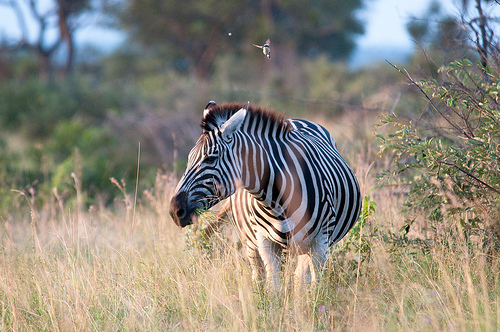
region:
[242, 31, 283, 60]
A small bird in flight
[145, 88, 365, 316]
A zebra standing in tall grass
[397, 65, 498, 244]
Green leafy small bush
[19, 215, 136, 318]
Grass drying in the sun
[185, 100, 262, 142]
A pair of zebra ears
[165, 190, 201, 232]
The snout of a zebra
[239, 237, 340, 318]
Zebra legs in the thick underbrush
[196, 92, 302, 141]
A zebras mane of hair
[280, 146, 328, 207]
Black and white zebra stripes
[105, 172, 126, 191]
A dry seed head on a shaft of grass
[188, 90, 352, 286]
a zebra is standing in the forest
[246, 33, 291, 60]
small bird flying above zebra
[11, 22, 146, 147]
trees with its branches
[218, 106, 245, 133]
ear of the zebra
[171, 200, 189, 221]
black colour nose of the zebra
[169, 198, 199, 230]
mouth of the zebra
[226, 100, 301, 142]
a hair on the zebra's neck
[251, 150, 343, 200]
brown with white colour stripes on the zebra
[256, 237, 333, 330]
legs of the zebra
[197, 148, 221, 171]
eys of the zebra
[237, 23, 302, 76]
Hummingbird hovering in air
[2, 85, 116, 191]
Lovely green shrubs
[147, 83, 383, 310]
Zabra staning by itself in field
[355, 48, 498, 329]
Bare shrubs with few leaves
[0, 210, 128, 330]
Dull colored grass in field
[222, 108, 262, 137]
White ear of a zebra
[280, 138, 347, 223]
Black and white stripes on Zebra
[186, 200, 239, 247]
Brown tree branch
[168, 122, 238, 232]
Lovely face of a zebra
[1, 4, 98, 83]
bare leefless trees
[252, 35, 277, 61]
a small hummingbird in flight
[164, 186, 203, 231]
the snout of a zebra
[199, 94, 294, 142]
the black and white mane of a zebra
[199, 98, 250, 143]
the ears of a zebra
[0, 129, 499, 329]
a field of dry dead grass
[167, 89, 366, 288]
a zebra eating grass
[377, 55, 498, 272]
a green bush with sparse leaves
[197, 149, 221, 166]
the eye of a zebra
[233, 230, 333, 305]
the legs of a zebra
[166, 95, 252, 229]
the head of a zebra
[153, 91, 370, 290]
zebra standing in tall grass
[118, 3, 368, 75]
tree in the middle background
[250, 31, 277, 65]
bird flying above zebra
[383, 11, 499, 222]
bush next to zebra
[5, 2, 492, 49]
skyline with trees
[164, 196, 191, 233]
the zebra's black snout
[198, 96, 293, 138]
the zebra's mane of short hair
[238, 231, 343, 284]
the zebra's legs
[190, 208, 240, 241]
the zebra's tail partially hidden by grass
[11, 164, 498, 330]
field of tall grass